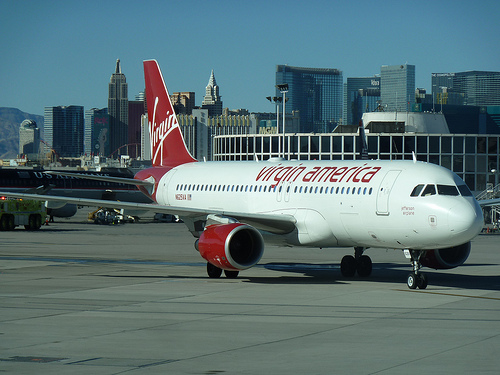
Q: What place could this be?
A: It is a park.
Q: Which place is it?
A: It is a park.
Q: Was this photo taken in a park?
A: Yes, it was taken in a park.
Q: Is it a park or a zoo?
A: It is a park.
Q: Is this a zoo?
A: No, it is a park.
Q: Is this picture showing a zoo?
A: No, the picture is showing a park.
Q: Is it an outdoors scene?
A: Yes, it is outdoors.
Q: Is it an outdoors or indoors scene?
A: It is outdoors.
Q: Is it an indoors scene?
A: No, it is outdoors.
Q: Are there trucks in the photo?
A: Yes, there is a truck.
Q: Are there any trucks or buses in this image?
A: Yes, there is a truck.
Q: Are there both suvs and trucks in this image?
A: No, there is a truck but no suvs.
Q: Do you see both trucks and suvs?
A: No, there is a truck but no suvs.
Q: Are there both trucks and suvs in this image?
A: No, there is a truck but no suvs.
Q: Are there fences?
A: No, there are no fences.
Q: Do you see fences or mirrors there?
A: No, there are no fences or mirrors.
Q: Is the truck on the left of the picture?
A: Yes, the truck is on the left of the image.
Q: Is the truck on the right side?
A: No, the truck is on the left of the image.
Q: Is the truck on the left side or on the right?
A: The truck is on the left of the image.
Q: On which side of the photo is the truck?
A: The truck is on the left of the image.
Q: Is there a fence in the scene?
A: No, there are no fences.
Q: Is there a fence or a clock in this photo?
A: No, there are no fences or clocks.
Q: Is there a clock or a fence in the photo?
A: No, there are no fences or clocks.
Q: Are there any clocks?
A: No, there are no clocks.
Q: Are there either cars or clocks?
A: No, there are no clocks or cars.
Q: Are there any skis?
A: No, there are no skis.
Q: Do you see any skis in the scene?
A: No, there are no skis.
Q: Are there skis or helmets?
A: No, there are no skis or helmets.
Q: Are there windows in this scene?
A: Yes, there is a window.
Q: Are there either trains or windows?
A: Yes, there is a window.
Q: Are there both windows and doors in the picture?
A: Yes, there are both a window and a door.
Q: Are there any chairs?
A: No, there are no chairs.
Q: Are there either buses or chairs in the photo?
A: No, there are no chairs or buses.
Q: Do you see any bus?
A: No, there are no buses.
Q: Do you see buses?
A: No, there are no buses.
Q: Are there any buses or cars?
A: No, there are no buses or cars.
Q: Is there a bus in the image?
A: No, there are no buses.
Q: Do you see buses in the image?
A: No, there are no buses.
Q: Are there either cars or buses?
A: No, there are no buses or cars.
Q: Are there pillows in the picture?
A: No, there are no pillows.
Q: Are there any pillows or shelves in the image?
A: No, there are no pillows or shelves.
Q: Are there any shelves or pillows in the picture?
A: No, there are no pillows or shelves.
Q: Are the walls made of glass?
A: Yes, the walls are made of glass.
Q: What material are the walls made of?
A: The walls are made of glass.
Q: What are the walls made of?
A: The walls are made of glass.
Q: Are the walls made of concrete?
A: No, the walls are made of glass.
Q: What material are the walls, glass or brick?
A: The walls are made of glass.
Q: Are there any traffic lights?
A: No, there are no traffic lights.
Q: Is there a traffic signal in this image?
A: No, there are no traffic lights.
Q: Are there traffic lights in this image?
A: No, there are no traffic lights.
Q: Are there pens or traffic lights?
A: No, there are no traffic lights or pens.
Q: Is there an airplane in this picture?
A: Yes, there is an airplane.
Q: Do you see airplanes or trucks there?
A: Yes, there is an airplane.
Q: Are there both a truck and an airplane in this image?
A: Yes, there are both an airplane and a truck.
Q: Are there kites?
A: No, there are no kites.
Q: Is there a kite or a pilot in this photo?
A: No, there are no kites or pilots.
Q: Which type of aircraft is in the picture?
A: The aircraft is an airplane.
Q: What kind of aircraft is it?
A: The aircraft is an airplane.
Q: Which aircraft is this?
A: This is an airplane.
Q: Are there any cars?
A: No, there are no cars.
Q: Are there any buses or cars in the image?
A: No, there are no cars or buses.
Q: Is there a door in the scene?
A: Yes, there is a door.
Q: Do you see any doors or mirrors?
A: Yes, there is a door.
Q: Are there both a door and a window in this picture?
A: Yes, there are both a door and a window.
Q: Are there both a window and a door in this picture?
A: Yes, there are both a door and a window.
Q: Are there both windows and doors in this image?
A: Yes, there are both a door and a window.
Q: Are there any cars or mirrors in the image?
A: No, there are no cars or mirrors.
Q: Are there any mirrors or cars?
A: No, there are no cars or mirrors.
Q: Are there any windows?
A: Yes, there are windows.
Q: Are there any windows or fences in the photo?
A: Yes, there are windows.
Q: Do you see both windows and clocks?
A: No, there are windows but no clocks.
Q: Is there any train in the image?
A: No, there are no trains.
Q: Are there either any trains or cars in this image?
A: No, there are no trains or cars.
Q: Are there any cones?
A: No, there are no cones.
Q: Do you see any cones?
A: No, there are no cones.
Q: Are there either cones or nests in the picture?
A: No, there are no cones or nests.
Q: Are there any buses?
A: No, there are no buses.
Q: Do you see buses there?
A: No, there are no buses.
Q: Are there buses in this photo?
A: No, there are no buses.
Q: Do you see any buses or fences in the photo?
A: No, there are no buses or fences.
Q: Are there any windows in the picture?
A: Yes, there are windows.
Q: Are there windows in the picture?
A: Yes, there are windows.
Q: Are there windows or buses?
A: Yes, there are windows.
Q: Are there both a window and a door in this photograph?
A: Yes, there are both a window and a door.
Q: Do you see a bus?
A: No, there are no buses.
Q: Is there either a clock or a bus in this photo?
A: No, there are no buses or clocks.